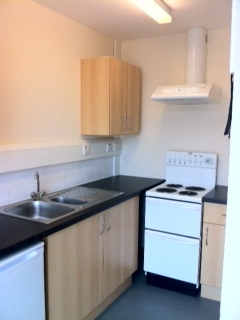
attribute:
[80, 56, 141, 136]
cabinets — wood, wooden, light brown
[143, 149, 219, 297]
stove — white, slim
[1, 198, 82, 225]
sink — aluminum, brushed, silver, on the left, shiny, metal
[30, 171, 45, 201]
faucet — chrome, metal, silver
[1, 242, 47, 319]
dishwasher — white, on the left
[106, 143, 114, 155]
electrical outlet — white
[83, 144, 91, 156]
electrical outlet — white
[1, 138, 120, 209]
tile — white, tiled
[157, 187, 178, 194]
electric burner — black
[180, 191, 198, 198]
electric burner — black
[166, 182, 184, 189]
electric burner — black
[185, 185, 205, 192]
electric burner — black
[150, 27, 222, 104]
electric vent — white, shiny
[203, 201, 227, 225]
drawer — wooden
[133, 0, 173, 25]
light — fluorescent, overhead, long, tubing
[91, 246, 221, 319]
floor — dark grey, blue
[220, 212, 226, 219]
drawer pull — metal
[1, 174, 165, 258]
counter top — dark, black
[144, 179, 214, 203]
stove top — white